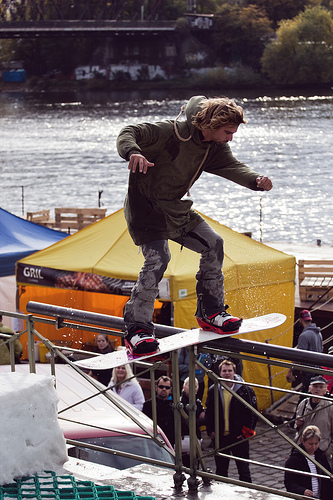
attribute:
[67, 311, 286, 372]
board — white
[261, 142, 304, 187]
water — sparkling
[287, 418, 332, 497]
woman — reading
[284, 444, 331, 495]
coat — black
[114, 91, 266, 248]
jacket — green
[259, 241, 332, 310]
deck — wooden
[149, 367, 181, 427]
man — standing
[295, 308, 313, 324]
hat — red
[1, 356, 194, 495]
vehicle — red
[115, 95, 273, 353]
man — wearing, snowboarding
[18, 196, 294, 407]
tent — yellow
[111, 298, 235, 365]
boots — white, red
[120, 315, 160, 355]
snow boot — black, red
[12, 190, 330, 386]
tent — yellow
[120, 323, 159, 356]
shoe — white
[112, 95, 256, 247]
hoodie — green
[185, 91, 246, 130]
hair — blonde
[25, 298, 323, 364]
rail — grey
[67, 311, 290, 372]
snowboard — white